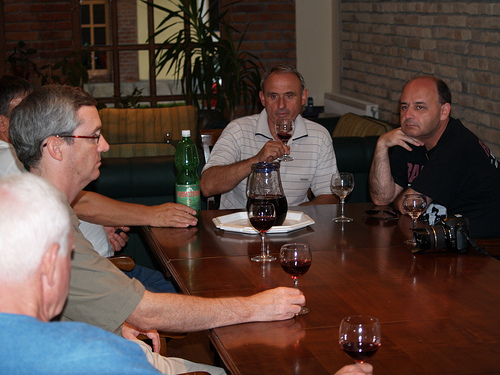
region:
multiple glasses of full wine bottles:
[268, 238, 374, 372]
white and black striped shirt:
[216, 100, 323, 194]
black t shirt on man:
[359, 146, 498, 191]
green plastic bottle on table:
[167, 143, 235, 280]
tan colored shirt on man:
[72, 247, 156, 328]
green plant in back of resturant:
[145, 9, 304, 126]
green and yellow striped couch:
[87, 75, 181, 162]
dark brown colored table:
[326, 262, 385, 308]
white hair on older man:
[10, 175, 105, 317]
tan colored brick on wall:
[331, 30, 478, 71]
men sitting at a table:
[28, 43, 497, 358]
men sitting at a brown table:
[5, 41, 472, 373]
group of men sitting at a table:
[14, 26, 498, 330]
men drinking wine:
[12, 33, 497, 308]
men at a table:
[19, 46, 498, 358]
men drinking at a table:
[22, 18, 494, 316]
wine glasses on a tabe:
[187, 157, 497, 360]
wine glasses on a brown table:
[169, 166, 474, 372]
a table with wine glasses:
[180, 143, 495, 357]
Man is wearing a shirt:
[1, 305, 171, 374]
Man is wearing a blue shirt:
[0, 308, 167, 373]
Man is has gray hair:
[0, 173, 75, 291]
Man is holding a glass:
[336, 311, 383, 373]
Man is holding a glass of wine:
[337, 312, 384, 373]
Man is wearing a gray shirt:
[30, 181, 149, 335]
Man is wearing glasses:
[43, 127, 105, 148]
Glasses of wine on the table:
[246, 175, 435, 371]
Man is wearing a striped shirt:
[188, 109, 343, 209]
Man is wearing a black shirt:
[383, 117, 497, 225]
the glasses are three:
[245, 208, 399, 363]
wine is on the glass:
[338, 311, 390, 370]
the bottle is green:
[163, 134, 211, 212]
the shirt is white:
[223, 123, 329, 201]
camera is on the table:
[405, 210, 469, 252]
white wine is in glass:
[325, 172, 366, 223]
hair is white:
[10, 176, 69, 261]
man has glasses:
[26, 103, 128, 185]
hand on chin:
[373, 128, 437, 163]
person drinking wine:
[223, 84, 325, 229]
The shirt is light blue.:
[1, 310, 167, 373]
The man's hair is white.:
[0, 172, 73, 279]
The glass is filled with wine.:
[276, 241, 312, 287]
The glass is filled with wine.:
[338, 313, 380, 361]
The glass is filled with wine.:
[246, 198, 278, 263]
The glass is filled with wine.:
[273, 114, 295, 144]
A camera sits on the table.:
[409, 211, 471, 258]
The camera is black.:
[408, 215, 480, 258]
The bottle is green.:
[172, 128, 202, 218]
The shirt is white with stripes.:
[201, 110, 341, 208]